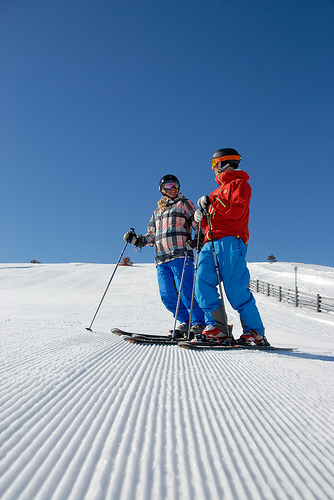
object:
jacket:
[199, 169, 254, 245]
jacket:
[131, 193, 199, 266]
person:
[191, 145, 267, 348]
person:
[123, 175, 202, 339]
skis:
[177, 336, 298, 353]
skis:
[110, 327, 192, 348]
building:
[30, 259, 40, 266]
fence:
[247, 274, 333, 317]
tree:
[263, 254, 277, 266]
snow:
[0, 258, 332, 498]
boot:
[198, 323, 228, 341]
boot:
[238, 326, 270, 347]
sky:
[0, 0, 334, 268]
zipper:
[206, 175, 224, 241]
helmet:
[209, 146, 243, 171]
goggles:
[208, 155, 242, 169]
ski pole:
[186, 216, 201, 343]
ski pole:
[202, 207, 234, 348]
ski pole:
[171, 239, 191, 342]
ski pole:
[87, 227, 134, 332]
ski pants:
[193, 236, 266, 339]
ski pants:
[154, 253, 201, 328]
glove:
[195, 195, 208, 210]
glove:
[193, 208, 203, 224]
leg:
[193, 241, 227, 332]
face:
[163, 182, 181, 200]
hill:
[246, 255, 334, 304]